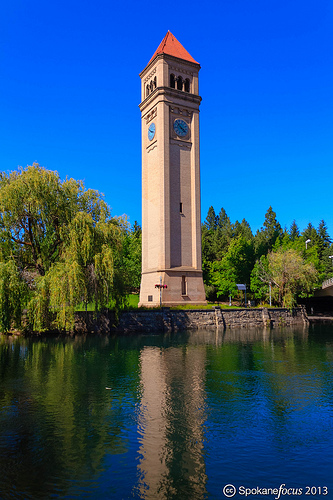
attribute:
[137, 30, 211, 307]
tower — stone, tall, thin, brown, tan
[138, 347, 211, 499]
reflection — brown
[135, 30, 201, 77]
roof — red, pointy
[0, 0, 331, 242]
sky — blue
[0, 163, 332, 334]
trees — green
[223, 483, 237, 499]
cc — white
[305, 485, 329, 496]
year — white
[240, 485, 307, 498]
name — white